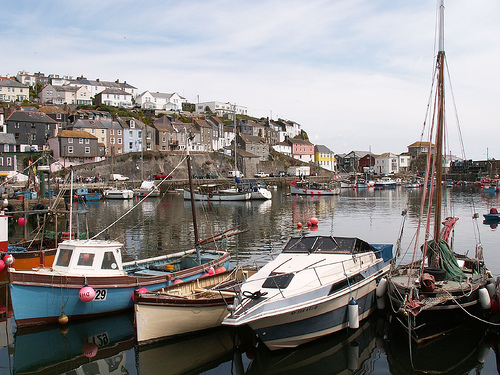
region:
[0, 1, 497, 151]
cloud cover in sky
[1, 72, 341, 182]
buildings on side of hill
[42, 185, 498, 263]
surface of calm water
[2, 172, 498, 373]
anchored boats in harbor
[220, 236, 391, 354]
bow of speed boat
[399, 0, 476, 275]
mast with no sail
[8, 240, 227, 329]
blue and brown fishing boat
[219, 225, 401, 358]
second boat is blue and white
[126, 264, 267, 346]
small boat is brown and tan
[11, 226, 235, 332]
boat is blue and brown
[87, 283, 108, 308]
number 29 is on blue boat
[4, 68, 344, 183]
row of buildings on hillside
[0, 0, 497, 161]
sky is mostly cloudy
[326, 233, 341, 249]
wipers on boat window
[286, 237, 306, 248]
wiper on second window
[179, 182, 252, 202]
long white boat in water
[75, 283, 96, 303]
pink ball hanging from boat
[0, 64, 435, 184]
houses and buildings in the background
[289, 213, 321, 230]
fishing ball floats on the water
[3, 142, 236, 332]
a blue fishing boat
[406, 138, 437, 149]
a roof of the building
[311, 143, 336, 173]
a yellow and white building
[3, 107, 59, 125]
a roof of the building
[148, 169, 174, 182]
a red truck on the road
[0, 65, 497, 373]
a fishing village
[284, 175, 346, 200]
a boat in the water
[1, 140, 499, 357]
empty boats docked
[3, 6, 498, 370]
a fishing village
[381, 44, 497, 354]
a fishing boat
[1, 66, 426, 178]
buildings in the background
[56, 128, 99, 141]
a roof of the building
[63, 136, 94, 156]
windows of the building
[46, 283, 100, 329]
fishing ball floats hanging on boat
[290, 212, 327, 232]
fishing ball floats on water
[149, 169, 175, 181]
a red truck on road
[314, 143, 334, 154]
roof of the building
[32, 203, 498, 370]
boats on the water